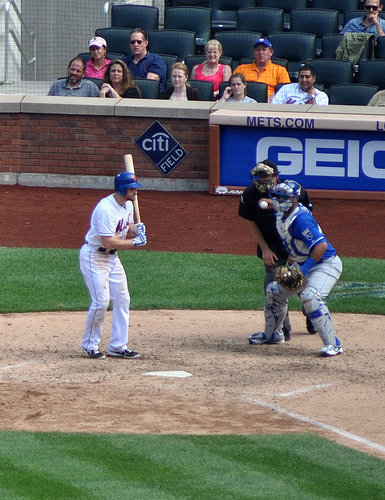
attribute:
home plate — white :
[142, 370, 192, 378]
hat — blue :
[254, 37, 271, 47]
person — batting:
[77, 168, 148, 361]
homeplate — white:
[142, 368, 192, 383]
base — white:
[140, 367, 194, 381]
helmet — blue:
[112, 173, 140, 195]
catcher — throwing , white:
[247, 178, 343, 356]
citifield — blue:
[140, 132, 184, 177]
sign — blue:
[130, 121, 188, 177]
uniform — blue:
[261, 206, 342, 349]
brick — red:
[2, 114, 209, 179]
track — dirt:
[1, 309, 383, 465]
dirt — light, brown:
[0, 305, 382, 460]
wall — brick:
[2, 94, 381, 262]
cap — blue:
[252, 38, 275, 48]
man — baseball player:
[75, 172, 147, 361]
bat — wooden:
[121, 155, 146, 246]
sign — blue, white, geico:
[215, 123, 383, 198]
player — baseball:
[75, 171, 147, 364]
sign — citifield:
[134, 118, 188, 174]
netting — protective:
[1, 2, 383, 117]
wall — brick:
[5, 91, 383, 200]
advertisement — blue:
[215, 119, 383, 194]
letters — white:
[253, 130, 302, 181]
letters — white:
[301, 134, 345, 178]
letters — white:
[345, 136, 360, 179]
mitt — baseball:
[274, 261, 307, 291]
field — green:
[3, 243, 381, 499]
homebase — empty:
[140, 364, 194, 385]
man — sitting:
[233, 36, 289, 101]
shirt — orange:
[234, 63, 288, 102]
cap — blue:
[253, 36, 271, 47]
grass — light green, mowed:
[36, 436, 304, 486]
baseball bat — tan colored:
[123, 151, 139, 223]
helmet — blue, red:
[112, 172, 142, 193]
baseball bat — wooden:
[122, 154, 142, 221]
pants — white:
[79, 244, 129, 349]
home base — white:
[141, 348, 213, 404]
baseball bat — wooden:
[116, 146, 151, 237]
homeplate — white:
[130, 364, 207, 396]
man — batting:
[59, 137, 171, 386]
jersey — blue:
[287, 214, 337, 260]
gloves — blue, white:
[129, 221, 149, 251]